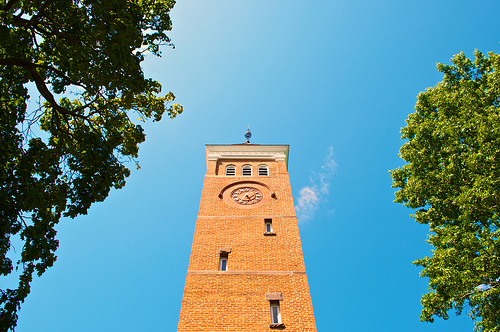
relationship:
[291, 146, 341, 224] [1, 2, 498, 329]
cloud in sky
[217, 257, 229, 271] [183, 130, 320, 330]
window on building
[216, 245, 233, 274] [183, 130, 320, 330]
window on building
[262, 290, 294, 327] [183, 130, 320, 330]
window on building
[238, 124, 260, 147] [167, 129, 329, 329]
object on building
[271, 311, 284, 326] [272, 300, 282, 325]
part of window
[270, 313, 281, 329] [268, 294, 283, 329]
part of window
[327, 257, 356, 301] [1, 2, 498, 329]
part of sky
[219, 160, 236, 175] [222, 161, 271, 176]
window forming row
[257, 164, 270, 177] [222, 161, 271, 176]
window forming row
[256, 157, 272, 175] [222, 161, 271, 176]
window forming row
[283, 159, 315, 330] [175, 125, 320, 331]
edge bordering building